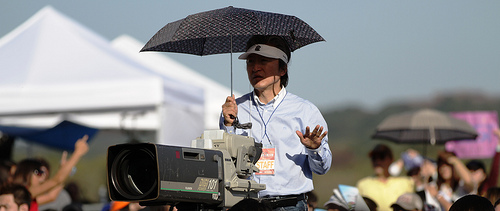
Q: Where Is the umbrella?
A: Over the man's head.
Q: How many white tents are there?
A: Two.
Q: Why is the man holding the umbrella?
A: Shade.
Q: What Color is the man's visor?
A: White.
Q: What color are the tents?
A: White.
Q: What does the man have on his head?
A: Visor.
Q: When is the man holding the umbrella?
A: Daytime.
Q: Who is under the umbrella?
A: The man in the visor.